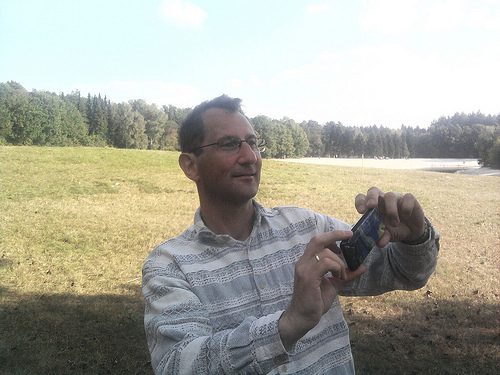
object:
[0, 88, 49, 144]
tree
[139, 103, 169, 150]
tree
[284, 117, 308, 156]
tree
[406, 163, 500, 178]
lake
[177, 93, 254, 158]
hair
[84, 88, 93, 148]
tall tree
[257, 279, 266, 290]
button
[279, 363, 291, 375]
button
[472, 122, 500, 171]
trees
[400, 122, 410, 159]
trees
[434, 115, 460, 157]
trees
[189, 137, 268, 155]
glasses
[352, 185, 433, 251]
man's hand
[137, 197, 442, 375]
shirt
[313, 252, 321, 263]
ring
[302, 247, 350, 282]
finger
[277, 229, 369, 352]
hand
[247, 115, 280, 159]
tree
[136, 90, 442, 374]
man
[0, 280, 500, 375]
shadow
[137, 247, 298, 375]
sleeve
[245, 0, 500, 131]
clouds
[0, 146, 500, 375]
field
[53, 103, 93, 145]
tree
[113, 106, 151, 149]
tree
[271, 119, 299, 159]
tree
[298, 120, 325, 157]
tree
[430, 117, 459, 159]
tree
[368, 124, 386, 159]
tree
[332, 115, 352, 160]
tree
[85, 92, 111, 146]
tree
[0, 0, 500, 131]
sky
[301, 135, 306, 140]
leaf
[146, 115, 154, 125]
leaf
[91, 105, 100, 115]
leaf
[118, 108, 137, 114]
leaf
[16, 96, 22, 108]
leaf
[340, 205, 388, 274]
phone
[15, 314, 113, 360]
grass